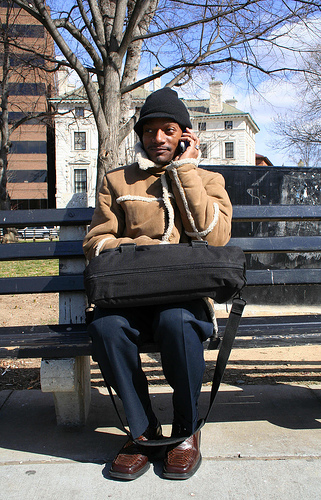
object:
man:
[82, 86, 232, 469]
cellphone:
[177, 142, 186, 154]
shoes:
[111, 419, 162, 483]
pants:
[88, 307, 213, 440]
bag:
[84, 240, 247, 445]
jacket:
[83, 143, 233, 263]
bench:
[1, 201, 321, 355]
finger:
[179, 136, 196, 148]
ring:
[193, 144, 201, 150]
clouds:
[237, 66, 295, 117]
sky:
[187, 16, 237, 41]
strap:
[214, 310, 239, 369]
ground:
[215, 434, 275, 461]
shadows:
[227, 388, 298, 408]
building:
[179, 76, 259, 169]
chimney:
[207, 77, 222, 114]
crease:
[173, 330, 194, 380]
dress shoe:
[163, 429, 201, 477]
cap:
[133, 86, 191, 135]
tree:
[58, 14, 135, 123]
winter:
[14, 9, 310, 289]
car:
[19, 226, 60, 237]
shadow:
[12, 399, 62, 450]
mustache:
[147, 146, 170, 150]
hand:
[180, 126, 200, 161]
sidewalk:
[247, 319, 298, 363]